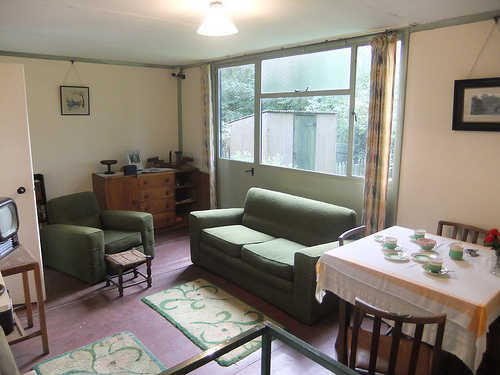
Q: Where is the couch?
A: By window.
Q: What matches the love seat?
A: Green chair.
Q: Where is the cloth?
A: On table.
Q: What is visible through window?
A: Shed.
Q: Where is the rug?
A: On the floor.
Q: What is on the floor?
A: A rug.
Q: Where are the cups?
A: On the table.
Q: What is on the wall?
A: Picture frame.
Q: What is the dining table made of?
A: Wood.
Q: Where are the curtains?
A: On the wall.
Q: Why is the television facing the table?
A: So that people who are eating can watch.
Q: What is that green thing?
A: Sitting furniture.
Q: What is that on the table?
A: Drinking tea cups.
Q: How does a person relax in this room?
A: By sitting on the green couch.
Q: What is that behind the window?
A: The shed.